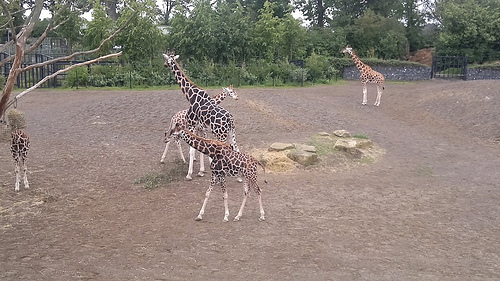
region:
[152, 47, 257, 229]
these are the giraffes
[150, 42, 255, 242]
they are the three in number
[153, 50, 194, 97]
the giraffe has long neck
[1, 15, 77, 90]
the tree is branchy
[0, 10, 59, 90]
the branches are dry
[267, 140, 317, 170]
these are rocks in the middle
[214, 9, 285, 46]
the leaves are green in color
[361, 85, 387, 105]
the legs are long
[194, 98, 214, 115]
the giraffe is brown and white in color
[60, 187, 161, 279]
the ground is brown in color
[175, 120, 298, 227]
this is a giraffe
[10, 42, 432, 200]
they are five giraffes in number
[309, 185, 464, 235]
this is a ground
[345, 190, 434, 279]
the ground is bare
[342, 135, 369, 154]
this is a rock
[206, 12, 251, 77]
this is a tree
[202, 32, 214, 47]
the tree has green leaves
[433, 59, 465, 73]
this is a gate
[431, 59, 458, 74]
the gate is metallic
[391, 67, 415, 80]
this is a wall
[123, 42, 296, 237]
Three giraffes standing together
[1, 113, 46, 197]
Baby giraffe standing alone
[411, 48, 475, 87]
Black wrot iron fence gate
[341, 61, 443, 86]
Stone wall leading to gate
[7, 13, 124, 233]
Leafless tree branches coming from left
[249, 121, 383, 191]
Rocks in the middle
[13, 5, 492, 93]
Man trees surrounding giraffes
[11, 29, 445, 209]
Five giraffes in a pen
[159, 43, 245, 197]
One giraffe is darker than the others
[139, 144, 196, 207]
little bit of grass by giraffes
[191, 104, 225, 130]
the fur is brown in color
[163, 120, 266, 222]
the giraffe is tall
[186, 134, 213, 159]
the neck is long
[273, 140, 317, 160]
these are some rocks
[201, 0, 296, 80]
these are some trees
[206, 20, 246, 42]
the leaves are green in color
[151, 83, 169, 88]
this is the grass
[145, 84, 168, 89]
the grass is green in color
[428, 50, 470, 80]
this is a gate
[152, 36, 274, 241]
giraffes standing up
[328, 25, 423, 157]
a giraffe standing up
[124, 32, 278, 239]
a giraffe standing in a field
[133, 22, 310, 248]
a giraffe walking during the day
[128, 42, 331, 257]
three giraffes walking in a field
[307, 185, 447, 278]
a dirt field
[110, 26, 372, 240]
a dirt field with giraffes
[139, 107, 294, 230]
a giraffe with his head down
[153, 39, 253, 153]
a giraffe with his head up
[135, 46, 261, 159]
a giraffe with his neck up